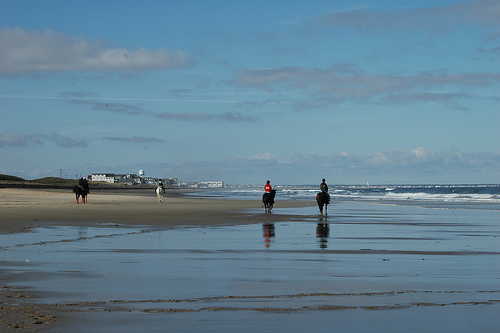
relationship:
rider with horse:
[261, 178, 268, 187] [260, 197, 292, 219]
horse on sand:
[260, 197, 292, 219] [107, 207, 144, 227]